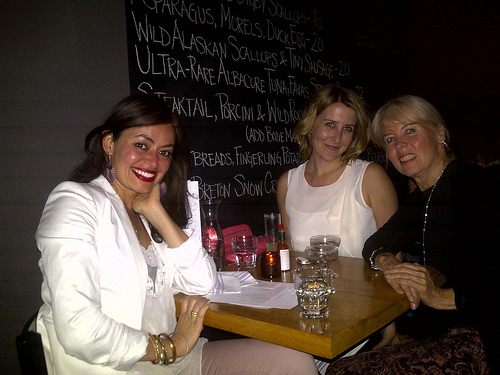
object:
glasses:
[230, 235, 259, 269]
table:
[174, 243, 450, 362]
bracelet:
[158, 332, 177, 364]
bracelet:
[148, 333, 162, 366]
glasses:
[291, 265, 332, 319]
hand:
[384, 261, 440, 305]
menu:
[130, 0, 393, 202]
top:
[90, 0, 429, 42]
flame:
[266, 252, 275, 263]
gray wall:
[1, 0, 125, 141]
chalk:
[192, 97, 203, 117]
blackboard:
[125, 0, 407, 207]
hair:
[371, 95, 450, 150]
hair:
[294, 82, 373, 167]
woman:
[271, 82, 397, 259]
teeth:
[132, 167, 155, 178]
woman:
[315, 90, 498, 375]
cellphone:
[296, 255, 314, 265]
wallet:
[205, 222, 277, 264]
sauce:
[278, 244, 289, 263]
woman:
[28, 92, 317, 375]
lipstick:
[133, 164, 155, 182]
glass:
[310, 233, 340, 263]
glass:
[231, 235, 258, 269]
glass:
[263, 212, 282, 253]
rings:
[191, 311, 198, 315]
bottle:
[277, 224, 292, 272]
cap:
[278, 224, 285, 229]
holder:
[260, 251, 282, 279]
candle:
[260, 250, 283, 278]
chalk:
[207, 68, 218, 86]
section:
[3, 3, 73, 142]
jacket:
[32, 172, 221, 374]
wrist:
[375, 255, 399, 265]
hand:
[381, 261, 421, 311]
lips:
[132, 167, 158, 183]